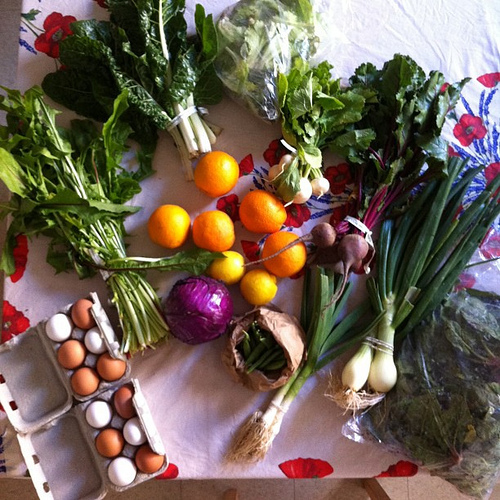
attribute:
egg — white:
[45, 311, 71, 340]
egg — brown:
[57, 337, 86, 369]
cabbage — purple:
[166, 279, 232, 348]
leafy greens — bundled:
[6, 5, 215, 359]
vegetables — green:
[1, 0, 497, 500]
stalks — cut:
[229, 152, 491, 463]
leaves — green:
[42, 4, 211, 124]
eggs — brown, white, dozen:
[38, 299, 195, 498]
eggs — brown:
[67, 351, 129, 398]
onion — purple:
[139, 270, 222, 328]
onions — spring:
[244, 225, 420, 456]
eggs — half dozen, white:
[38, 275, 189, 496]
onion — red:
[163, 273, 233, 345]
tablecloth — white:
[3, 1, 489, 481]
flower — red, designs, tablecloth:
[1, 7, 496, 476]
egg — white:
[42, 309, 72, 344]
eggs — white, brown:
[78, 371, 143, 480]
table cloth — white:
[0, 0, 499, 480]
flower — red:
[452, 113, 487, 145]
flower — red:
[322, 162, 351, 194]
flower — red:
[2, 300, 29, 342]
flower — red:
[217, 192, 239, 219]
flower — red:
[34, 12, 77, 56]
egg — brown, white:
[41, 312, 71, 342]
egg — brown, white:
[68, 295, 98, 329]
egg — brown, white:
[80, 328, 106, 353]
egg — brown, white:
[53, 339, 85, 368]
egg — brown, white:
[93, 354, 128, 382]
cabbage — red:
[163, 275, 233, 345]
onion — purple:
[165, 277, 230, 341]